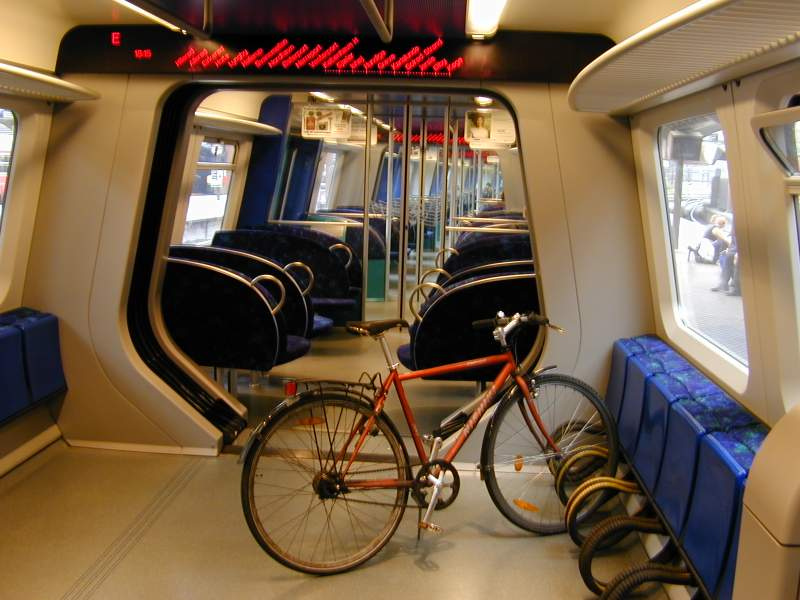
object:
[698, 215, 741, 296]
person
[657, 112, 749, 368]
window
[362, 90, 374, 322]
pole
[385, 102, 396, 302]
pole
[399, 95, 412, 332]
pole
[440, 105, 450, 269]
pole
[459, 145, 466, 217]
pole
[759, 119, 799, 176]
window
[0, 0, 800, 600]
train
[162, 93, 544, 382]
row